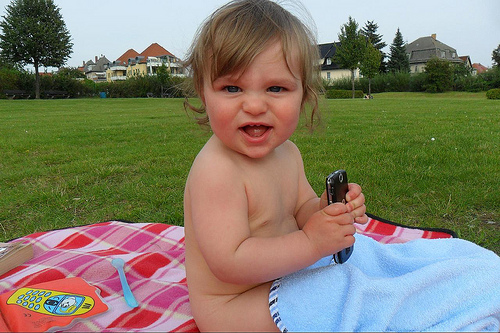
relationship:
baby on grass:
[187, 4, 363, 332] [1, 93, 498, 251]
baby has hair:
[187, 4, 363, 332] [171, 8, 325, 133]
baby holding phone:
[187, 4, 363, 332] [323, 175, 359, 269]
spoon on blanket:
[111, 252, 140, 310] [5, 223, 499, 332]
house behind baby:
[298, 41, 365, 89] [187, 4, 363, 332]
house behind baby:
[106, 47, 186, 94] [187, 4, 363, 332]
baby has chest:
[187, 4, 363, 332] [237, 173, 302, 230]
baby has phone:
[187, 4, 363, 332] [323, 175, 359, 269]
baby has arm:
[187, 4, 363, 332] [191, 173, 352, 280]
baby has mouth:
[187, 4, 363, 332] [235, 119, 275, 144]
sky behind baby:
[3, 1, 499, 79] [187, 4, 363, 332]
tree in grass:
[7, 2, 65, 106] [1, 93, 498, 251]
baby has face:
[187, 4, 363, 332] [208, 52, 300, 157]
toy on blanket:
[3, 273, 111, 332] [5, 223, 499, 332]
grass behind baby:
[1, 93, 498, 251] [187, 4, 363, 332]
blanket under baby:
[5, 223, 499, 332] [187, 4, 363, 332]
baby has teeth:
[187, 4, 363, 332] [250, 122, 263, 129]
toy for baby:
[3, 273, 111, 332] [187, 4, 363, 332]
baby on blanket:
[187, 4, 363, 332] [5, 223, 499, 332]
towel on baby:
[271, 227, 499, 333] [187, 4, 363, 332]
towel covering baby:
[271, 227, 499, 333] [187, 4, 363, 332]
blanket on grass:
[5, 223, 499, 332] [1, 93, 498, 251]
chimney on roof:
[432, 34, 438, 42] [398, 35, 455, 52]